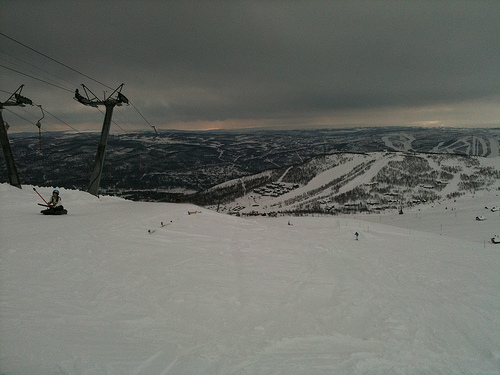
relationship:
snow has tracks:
[2, 179, 492, 371] [133, 217, 433, 357]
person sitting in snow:
[28, 188, 78, 220] [2, 179, 492, 371]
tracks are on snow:
[133, 217, 433, 357] [2, 179, 492, 371]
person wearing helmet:
[28, 188, 78, 220] [50, 186, 61, 198]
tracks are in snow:
[133, 217, 433, 357] [2, 179, 492, 371]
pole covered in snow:
[91, 101, 109, 212] [2, 179, 492, 371]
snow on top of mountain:
[2, 179, 492, 371] [5, 175, 500, 370]